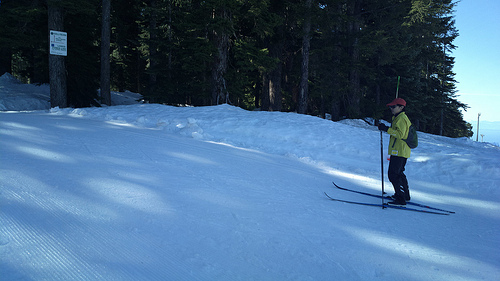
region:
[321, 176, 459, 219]
Person on skis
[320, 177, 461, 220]
Person is on skis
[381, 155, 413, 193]
Person wearing pants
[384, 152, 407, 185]
Person is wearing pants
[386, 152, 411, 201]
Person wearing black pants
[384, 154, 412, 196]
Person is wearing black pants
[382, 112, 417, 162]
Person wearing a yellow jacket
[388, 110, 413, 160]
Person is wearing a yellow jacket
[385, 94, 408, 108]
Person wearing a red hat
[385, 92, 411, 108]
Person is wearing a red hat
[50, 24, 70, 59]
white sign on tree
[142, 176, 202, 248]
snow on the ground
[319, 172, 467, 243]
a pair of skis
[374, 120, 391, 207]
pole in her left hand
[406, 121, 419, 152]
a small green backpack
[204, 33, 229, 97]
bark of the tree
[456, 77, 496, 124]
cloud in the background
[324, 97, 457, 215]
A lady on skis.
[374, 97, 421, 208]
A lady holding poles.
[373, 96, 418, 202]
A lady in the snow.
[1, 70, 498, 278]
Snow on a hill.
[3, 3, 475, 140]
Trees on a hill.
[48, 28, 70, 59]
A sign on a tree.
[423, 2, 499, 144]
A clear blue sky.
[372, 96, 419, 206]
A lady with a hat.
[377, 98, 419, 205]
A lady with a backpack.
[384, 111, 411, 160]
A jacket on a lady.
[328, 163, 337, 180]
part of a hill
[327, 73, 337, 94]
part of a bush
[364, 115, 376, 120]
part of a cloud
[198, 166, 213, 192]
part of a hill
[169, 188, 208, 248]
edge of a hill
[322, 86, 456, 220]
man on black skis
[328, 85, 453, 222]
skier with a yellow jacket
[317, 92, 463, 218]
skier with black pants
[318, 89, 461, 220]
skier with a red hat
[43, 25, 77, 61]
sign posted on a tree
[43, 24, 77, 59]
white sign on a tree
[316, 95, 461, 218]
skier at the edge of the trees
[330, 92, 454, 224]
person wearing sunglasses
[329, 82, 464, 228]
skier in the shadow of the trees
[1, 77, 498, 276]
white snow covering the ground